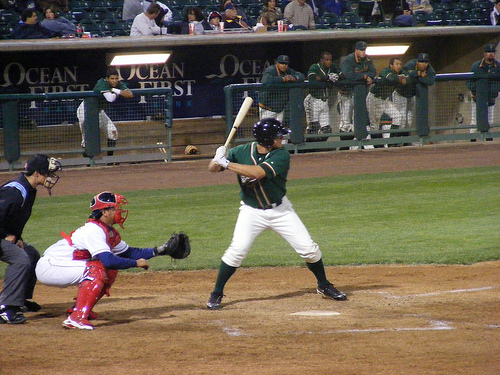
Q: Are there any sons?
A: No, there are no sons.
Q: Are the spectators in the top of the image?
A: Yes, the spectators are in the top of the image.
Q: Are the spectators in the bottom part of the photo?
A: No, the spectators are in the top of the image.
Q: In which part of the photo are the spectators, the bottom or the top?
A: The spectators are in the top of the image.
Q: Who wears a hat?
A: The player wears a hat.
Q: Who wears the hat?
A: The player wears a hat.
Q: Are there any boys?
A: No, there are no boys.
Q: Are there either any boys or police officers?
A: No, there are no boys or police officers.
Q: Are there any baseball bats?
A: Yes, there is a baseball bat.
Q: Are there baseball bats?
A: Yes, there is a baseball bat.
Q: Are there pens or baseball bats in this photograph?
A: Yes, there is a baseball bat.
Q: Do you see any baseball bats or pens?
A: Yes, there is a baseball bat.